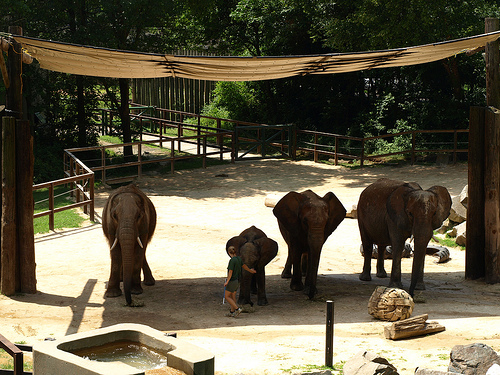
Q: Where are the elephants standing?
A: In the shade.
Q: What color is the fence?
A: Brown.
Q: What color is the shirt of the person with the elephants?
A: Green.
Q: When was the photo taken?
A: Daytime.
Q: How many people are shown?
A: One.